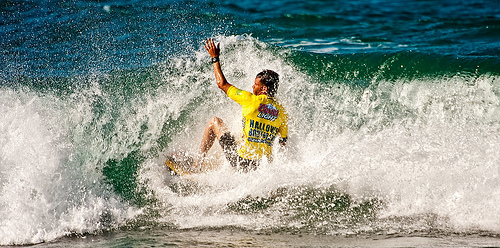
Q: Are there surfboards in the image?
A: Yes, there is a surfboard.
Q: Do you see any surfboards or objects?
A: Yes, there is a surfboard.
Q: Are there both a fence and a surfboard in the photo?
A: No, there is a surfboard but no fences.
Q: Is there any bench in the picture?
A: No, there are no benches.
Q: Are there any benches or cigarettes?
A: No, there are no benches or cigarettes.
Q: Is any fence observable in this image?
A: No, there are no fences.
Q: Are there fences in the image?
A: No, there are no fences.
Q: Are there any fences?
A: No, there are no fences.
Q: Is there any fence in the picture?
A: No, there are no fences.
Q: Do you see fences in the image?
A: No, there are no fences.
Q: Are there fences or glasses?
A: No, there are no fences or glasses.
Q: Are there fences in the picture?
A: No, there are no fences.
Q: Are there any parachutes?
A: No, there are no parachutes.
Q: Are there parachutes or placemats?
A: No, there are no parachutes or placemats.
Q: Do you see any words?
A: Yes, there are words.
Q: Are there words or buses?
A: Yes, there are words.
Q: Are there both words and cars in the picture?
A: No, there are words but no cars.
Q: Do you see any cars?
A: No, there are no cars.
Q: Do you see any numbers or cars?
A: No, there are no cars or numbers.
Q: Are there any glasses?
A: No, there are no glasses.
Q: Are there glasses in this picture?
A: No, there are no glasses.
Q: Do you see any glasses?
A: No, there are no glasses.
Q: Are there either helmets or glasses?
A: No, there are no glasses or helmets.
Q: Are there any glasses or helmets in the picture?
A: No, there are no glasses or helmets.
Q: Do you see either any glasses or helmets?
A: No, there are no glasses or helmets.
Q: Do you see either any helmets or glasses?
A: No, there are no glasses or helmets.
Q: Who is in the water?
A: The man is in the water.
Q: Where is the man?
A: The man is in the water.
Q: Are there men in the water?
A: Yes, there is a man in the water.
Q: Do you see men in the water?
A: Yes, there is a man in the water.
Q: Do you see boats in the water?
A: No, there is a man in the water.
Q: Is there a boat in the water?
A: No, there is a man in the water.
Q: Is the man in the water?
A: Yes, the man is in the water.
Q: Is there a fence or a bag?
A: No, there are no fences or bags.